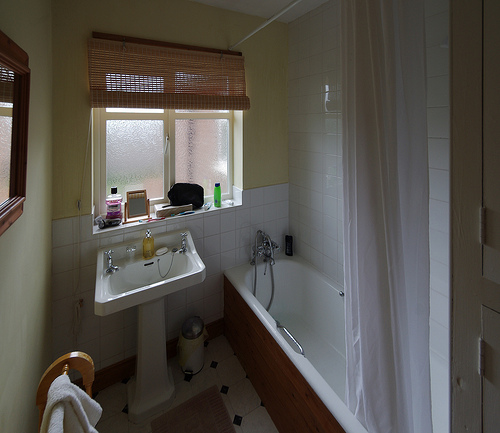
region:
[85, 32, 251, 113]
wood bamboo window shade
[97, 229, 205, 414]
white porcelain bathroom sink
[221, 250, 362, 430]
white porcelain bath tub with wood sides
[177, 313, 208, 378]
white and chrome waste basket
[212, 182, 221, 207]
green bottle of shampoo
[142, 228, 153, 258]
bottle of liquid hand soap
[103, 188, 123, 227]
a clear plastic bottle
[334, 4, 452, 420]
a white shower curtain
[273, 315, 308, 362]
a metal handrail in a tub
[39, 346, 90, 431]
a wood rack with a towel over it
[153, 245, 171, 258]
a bar of white soap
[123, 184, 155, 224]
a small mirror on a stand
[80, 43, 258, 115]
a blind covering a window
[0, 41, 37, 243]
a mirror hanging on a wall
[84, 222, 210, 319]
a white bathroom sink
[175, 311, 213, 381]
a garbage can with a lid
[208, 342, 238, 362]
THIS IS A TILE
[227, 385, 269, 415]
THIS IS A TILE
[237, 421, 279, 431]
THIS IS A TILE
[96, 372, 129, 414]
THIS IS A TILE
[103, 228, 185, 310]
THIS IS A SINK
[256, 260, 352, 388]
THIS IS A BATH TUB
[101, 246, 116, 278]
THIS IS A TAP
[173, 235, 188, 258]
THIS IS A TAP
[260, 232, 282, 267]
THIS IS A TAP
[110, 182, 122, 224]
THIS IS A SHOWER JEL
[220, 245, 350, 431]
white bathtub with wood side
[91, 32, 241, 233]
window with bamboo window shade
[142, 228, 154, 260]
yellow bottle of liquid soap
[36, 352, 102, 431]
wooden towel hanger with white towel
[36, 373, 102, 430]
white towel hanging on rack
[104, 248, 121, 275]
left bathroom faucet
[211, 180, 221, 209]
green bottle of shampoo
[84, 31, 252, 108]
bamboo window shade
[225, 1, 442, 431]
white shower curtain hanging above tub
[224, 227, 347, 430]
faucet hardware and hose above tub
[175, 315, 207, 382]
trash can with foot pedal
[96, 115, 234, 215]
two panes of frosted windpws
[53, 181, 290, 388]
white square tiles on wall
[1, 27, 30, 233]
mirror in wood frame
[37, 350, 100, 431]
white towel on wood rack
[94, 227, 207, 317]
sink with two faucets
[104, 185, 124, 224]
bottle with black cap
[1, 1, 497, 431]
interior of residential bathroom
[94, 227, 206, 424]
white square sink on pedestal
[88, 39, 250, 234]
items on window sill